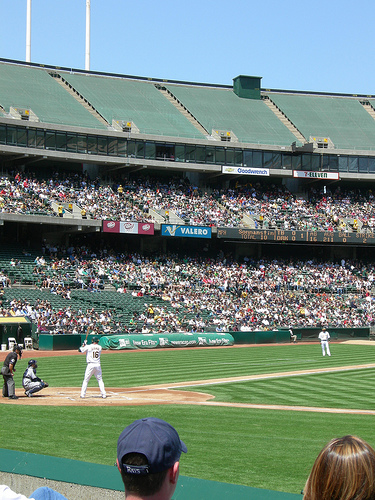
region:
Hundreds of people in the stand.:
[131, 262, 342, 324]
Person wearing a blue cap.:
[110, 399, 183, 466]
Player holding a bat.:
[85, 325, 104, 392]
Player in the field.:
[304, 321, 339, 366]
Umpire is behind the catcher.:
[8, 340, 51, 405]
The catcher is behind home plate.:
[29, 353, 92, 413]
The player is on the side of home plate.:
[73, 323, 110, 407]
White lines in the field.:
[184, 373, 328, 423]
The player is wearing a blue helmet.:
[25, 356, 43, 363]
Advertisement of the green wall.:
[92, 330, 245, 349]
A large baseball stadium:
[15, 82, 364, 477]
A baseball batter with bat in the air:
[75, 319, 112, 395]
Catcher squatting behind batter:
[19, 358, 40, 394]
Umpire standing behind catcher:
[4, 338, 23, 395]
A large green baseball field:
[163, 349, 304, 463]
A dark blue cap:
[114, 411, 192, 486]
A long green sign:
[99, 324, 240, 357]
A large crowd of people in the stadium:
[144, 272, 299, 317]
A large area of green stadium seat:
[30, 274, 141, 319]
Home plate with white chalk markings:
[52, 376, 174, 411]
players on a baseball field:
[1, 317, 118, 404]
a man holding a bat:
[76, 317, 107, 402]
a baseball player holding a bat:
[75, 315, 114, 405]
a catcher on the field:
[20, 354, 50, 400]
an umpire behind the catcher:
[0, 341, 49, 399]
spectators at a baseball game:
[155, 240, 363, 325]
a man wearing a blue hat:
[111, 418, 186, 478]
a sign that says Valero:
[160, 220, 216, 239]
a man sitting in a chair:
[286, 324, 301, 341]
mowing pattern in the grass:
[261, 379, 374, 408]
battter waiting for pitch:
[76, 332, 111, 401]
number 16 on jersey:
[89, 349, 101, 361]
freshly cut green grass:
[294, 382, 332, 401]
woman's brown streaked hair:
[324, 447, 372, 489]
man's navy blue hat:
[117, 418, 186, 471]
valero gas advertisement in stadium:
[164, 224, 218, 237]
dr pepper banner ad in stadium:
[106, 222, 158, 234]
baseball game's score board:
[276, 228, 307, 245]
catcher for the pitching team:
[21, 359, 48, 396]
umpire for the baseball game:
[0, 344, 24, 398]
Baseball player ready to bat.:
[75, 323, 116, 402]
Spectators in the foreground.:
[1, 414, 373, 498]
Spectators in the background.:
[1, 134, 371, 334]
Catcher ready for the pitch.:
[20, 356, 50, 399]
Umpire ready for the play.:
[0, 341, 24, 401]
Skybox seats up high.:
[2, 114, 373, 184]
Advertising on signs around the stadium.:
[92, 214, 237, 351]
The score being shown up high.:
[214, 219, 373, 245]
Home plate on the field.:
[90, 390, 113, 398]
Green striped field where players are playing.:
[4, 340, 373, 496]